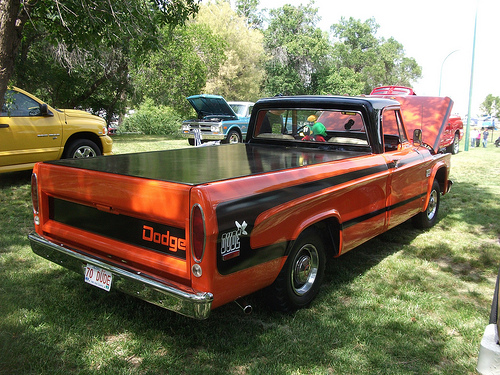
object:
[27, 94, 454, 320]
truck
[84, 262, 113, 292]
license plate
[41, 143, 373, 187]
black bed cover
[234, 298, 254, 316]
chrome exhaust pipe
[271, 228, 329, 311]
rear tire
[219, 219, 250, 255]
dude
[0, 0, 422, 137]
large trees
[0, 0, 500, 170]
background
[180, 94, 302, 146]
truck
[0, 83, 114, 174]
truck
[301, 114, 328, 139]
man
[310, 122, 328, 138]
shirt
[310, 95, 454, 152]
hood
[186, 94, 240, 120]
hood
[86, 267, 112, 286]
70 dude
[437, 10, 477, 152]
two light posts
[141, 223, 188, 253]
dodge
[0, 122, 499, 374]
grass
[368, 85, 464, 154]
truck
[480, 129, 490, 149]
people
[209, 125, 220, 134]
headlights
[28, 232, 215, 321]
chrome bumper